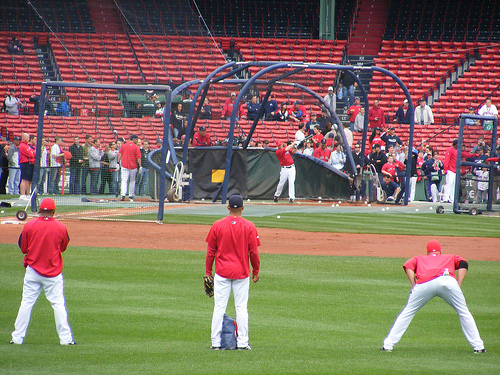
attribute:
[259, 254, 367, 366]
grass — green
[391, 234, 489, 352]
man — bent foreward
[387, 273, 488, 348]
pants — white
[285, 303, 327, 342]
grass — thick, green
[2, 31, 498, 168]
bleachers — red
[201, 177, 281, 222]
cap — blue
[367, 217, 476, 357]
man — red and white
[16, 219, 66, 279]
jersey — red and white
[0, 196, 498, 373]
field — dirt, grass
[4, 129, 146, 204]
crowd — watching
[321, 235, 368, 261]
dirt — clean looking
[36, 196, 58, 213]
cap — red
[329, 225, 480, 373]
player — bending over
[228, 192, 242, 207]
hat — black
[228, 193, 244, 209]
cap — black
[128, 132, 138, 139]
cap — black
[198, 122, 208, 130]
cap — black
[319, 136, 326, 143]
cap — black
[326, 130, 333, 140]
cap — black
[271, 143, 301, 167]
jersey — red and white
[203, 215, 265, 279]
baseball jersey — red and white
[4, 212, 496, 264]
dirt — brown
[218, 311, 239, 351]
bag — blue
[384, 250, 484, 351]
jersey — red and white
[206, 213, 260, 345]
jersey — red and white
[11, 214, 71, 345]
jersey — red and white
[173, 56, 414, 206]
frame — metal